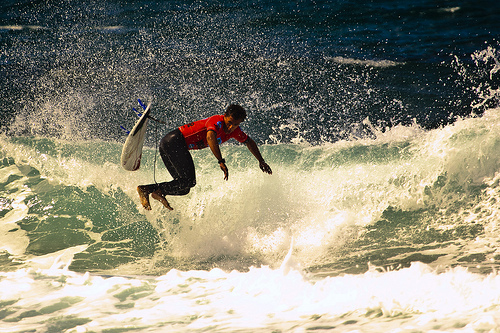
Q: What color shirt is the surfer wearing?
A: Red.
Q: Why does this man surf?
A: For sport.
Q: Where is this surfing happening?
A: At the beach.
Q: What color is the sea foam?
A: White.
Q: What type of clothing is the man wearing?
A: Waterproof.